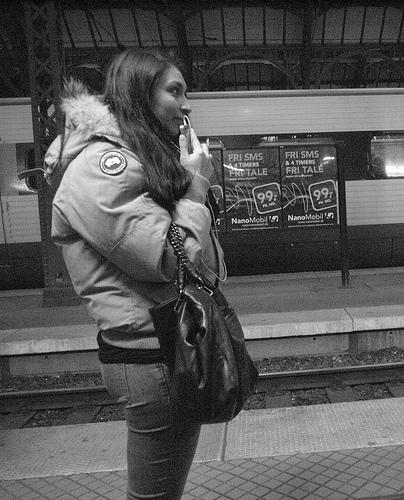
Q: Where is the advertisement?
A: On the train platform.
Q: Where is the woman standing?
A: On the train platform.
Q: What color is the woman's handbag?
A: Black.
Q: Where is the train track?
A: By the woman.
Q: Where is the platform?
A: Above the train tracks.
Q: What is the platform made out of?
A: Cement.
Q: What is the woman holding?
A: A big purse.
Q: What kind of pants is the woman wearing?
A: Jeans.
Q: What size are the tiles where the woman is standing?
A: Medium.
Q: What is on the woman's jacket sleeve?
A: A patch.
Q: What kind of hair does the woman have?
A: Long.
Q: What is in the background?
A: Train.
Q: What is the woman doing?
A: Waiting for the train.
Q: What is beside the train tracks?
A: Sidewalk.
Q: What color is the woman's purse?
A: Black.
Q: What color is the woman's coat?
A: Gray.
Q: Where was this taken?
A: Train station.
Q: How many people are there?
A: 1.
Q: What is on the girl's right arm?
A: Purse.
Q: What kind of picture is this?
A: Black and white.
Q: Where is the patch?
A: Girl's upper right arm.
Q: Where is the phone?
A: In the girl's hand.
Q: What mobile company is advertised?
A: Nanomobil.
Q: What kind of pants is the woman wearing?
A: Jeans.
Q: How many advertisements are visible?
A: 2.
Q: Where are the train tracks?
A: On the woman's left.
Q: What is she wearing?
A: A winter coat.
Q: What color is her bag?
A: Black.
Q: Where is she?
A: The train station.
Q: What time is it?
A: The evening.